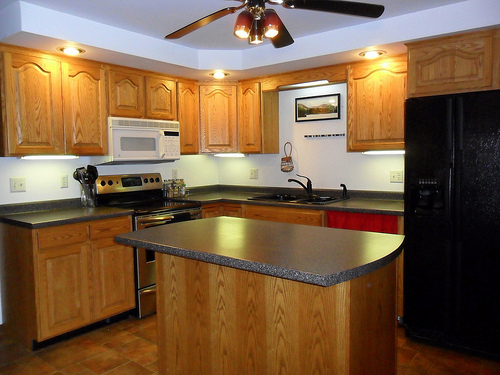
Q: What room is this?
A: It is a kitchen.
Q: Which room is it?
A: It is a kitchen.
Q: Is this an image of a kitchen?
A: Yes, it is showing a kitchen.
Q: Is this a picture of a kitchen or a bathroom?
A: It is showing a kitchen.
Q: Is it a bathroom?
A: No, it is a kitchen.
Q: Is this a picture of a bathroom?
A: No, the picture is showing a kitchen.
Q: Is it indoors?
A: Yes, it is indoors.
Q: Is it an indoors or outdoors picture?
A: It is indoors.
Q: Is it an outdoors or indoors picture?
A: It is indoors.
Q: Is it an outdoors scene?
A: No, it is indoors.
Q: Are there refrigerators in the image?
A: Yes, there is a refrigerator.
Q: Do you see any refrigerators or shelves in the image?
A: Yes, there is a refrigerator.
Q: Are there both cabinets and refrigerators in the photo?
A: Yes, there are both a refrigerator and a cabinet.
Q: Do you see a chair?
A: No, there are no chairs.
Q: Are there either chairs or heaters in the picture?
A: No, there are no chairs or heaters.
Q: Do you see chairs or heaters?
A: No, there are no chairs or heaters.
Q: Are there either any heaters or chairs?
A: No, there are no chairs or heaters.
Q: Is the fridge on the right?
A: Yes, the fridge is on the right of the image.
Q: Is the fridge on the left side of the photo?
A: No, the fridge is on the right of the image.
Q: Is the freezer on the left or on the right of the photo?
A: The freezer is on the right of the image.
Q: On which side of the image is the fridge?
A: The fridge is on the right of the image.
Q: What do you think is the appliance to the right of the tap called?
A: The appliance is a refrigerator.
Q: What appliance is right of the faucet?
A: The appliance is a refrigerator.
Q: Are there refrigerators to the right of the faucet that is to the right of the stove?
A: Yes, there is a refrigerator to the right of the tap.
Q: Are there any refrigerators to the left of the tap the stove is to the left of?
A: No, the refrigerator is to the right of the tap.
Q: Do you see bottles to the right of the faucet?
A: No, there is a refrigerator to the right of the faucet.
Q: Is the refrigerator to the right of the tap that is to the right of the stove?
A: Yes, the refrigerator is to the right of the tap.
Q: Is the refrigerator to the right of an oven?
A: No, the refrigerator is to the right of the tap.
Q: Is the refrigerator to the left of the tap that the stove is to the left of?
A: No, the refrigerator is to the right of the tap.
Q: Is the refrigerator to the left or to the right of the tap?
A: The refrigerator is to the right of the tap.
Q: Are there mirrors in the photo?
A: No, there are no mirrors.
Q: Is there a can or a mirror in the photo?
A: No, there are no mirrors or cans.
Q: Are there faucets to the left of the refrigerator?
A: Yes, there is a faucet to the left of the refrigerator.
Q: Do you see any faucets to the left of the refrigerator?
A: Yes, there is a faucet to the left of the refrigerator.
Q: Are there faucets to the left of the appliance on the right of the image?
A: Yes, there is a faucet to the left of the refrigerator.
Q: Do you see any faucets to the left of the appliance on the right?
A: Yes, there is a faucet to the left of the refrigerator.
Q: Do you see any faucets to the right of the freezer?
A: No, the faucet is to the left of the freezer.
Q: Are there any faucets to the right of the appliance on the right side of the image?
A: No, the faucet is to the left of the freezer.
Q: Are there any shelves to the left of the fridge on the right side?
A: No, there is a faucet to the left of the fridge.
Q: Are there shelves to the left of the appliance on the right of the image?
A: No, there is a faucet to the left of the fridge.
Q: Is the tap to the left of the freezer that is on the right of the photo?
A: Yes, the tap is to the left of the fridge.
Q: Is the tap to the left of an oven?
A: No, the tap is to the left of the fridge.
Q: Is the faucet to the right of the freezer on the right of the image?
A: No, the faucet is to the left of the fridge.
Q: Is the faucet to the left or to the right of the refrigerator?
A: The faucet is to the left of the refrigerator.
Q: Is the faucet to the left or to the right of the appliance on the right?
A: The faucet is to the left of the refrigerator.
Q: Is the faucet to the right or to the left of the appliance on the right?
A: The faucet is to the left of the refrigerator.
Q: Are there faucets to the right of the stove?
A: Yes, there is a faucet to the right of the stove.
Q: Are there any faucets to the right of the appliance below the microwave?
A: Yes, there is a faucet to the right of the stove.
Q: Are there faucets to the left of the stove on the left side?
A: No, the faucet is to the right of the stove.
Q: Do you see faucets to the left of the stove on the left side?
A: No, the faucet is to the right of the stove.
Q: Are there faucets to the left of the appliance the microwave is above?
A: No, the faucet is to the right of the stove.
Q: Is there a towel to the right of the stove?
A: No, there is a faucet to the right of the stove.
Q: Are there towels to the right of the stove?
A: No, there is a faucet to the right of the stove.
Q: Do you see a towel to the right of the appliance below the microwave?
A: No, there is a faucet to the right of the stove.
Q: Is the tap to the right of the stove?
A: Yes, the tap is to the right of the stove.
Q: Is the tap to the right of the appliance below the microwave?
A: Yes, the tap is to the right of the stove.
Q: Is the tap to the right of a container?
A: No, the tap is to the right of the stove.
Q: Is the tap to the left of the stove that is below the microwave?
A: No, the tap is to the right of the stove.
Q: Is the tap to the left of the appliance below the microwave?
A: No, the tap is to the right of the stove.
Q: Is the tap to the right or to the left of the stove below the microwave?
A: The tap is to the right of the stove.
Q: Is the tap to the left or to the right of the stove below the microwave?
A: The tap is to the right of the stove.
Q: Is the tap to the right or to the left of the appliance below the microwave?
A: The tap is to the right of the stove.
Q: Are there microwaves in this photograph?
A: Yes, there is a microwave.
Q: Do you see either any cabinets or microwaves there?
A: Yes, there is a microwave.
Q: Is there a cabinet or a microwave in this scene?
A: Yes, there is a microwave.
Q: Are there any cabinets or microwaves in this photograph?
A: Yes, there is a microwave.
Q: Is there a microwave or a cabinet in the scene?
A: Yes, there is a microwave.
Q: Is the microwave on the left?
A: Yes, the microwave is on the left of the image.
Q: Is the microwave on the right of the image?
A: No, the microwave is on the left of the image.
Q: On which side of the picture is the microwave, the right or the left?
A: The microwave is on the left of the image.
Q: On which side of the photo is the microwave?
A: The microwave is on the left of the image.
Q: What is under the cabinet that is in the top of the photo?
A: The microwave is under the cabinet.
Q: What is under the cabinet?
A: The microwave is under the cabinet.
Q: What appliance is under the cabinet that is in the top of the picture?
A: The appliance is a microwave.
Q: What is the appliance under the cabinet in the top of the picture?
A: The appliance is a microwave.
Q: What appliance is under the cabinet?
A: The appliance is a microwave.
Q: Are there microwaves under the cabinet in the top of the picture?
A: Yes, there is a microwave under the cabinet.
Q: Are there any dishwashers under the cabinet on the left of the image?
A: No, there is a microwave under the cabinet.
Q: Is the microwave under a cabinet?
A: Yes, the microwave is under a cabinet.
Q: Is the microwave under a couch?
A: No, the microwave is under a cabinet.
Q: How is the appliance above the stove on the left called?
A: The appliance is a microwave.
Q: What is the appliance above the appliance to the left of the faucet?
A: The appliance is a microwave.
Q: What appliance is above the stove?
A: The appliance is a microwave.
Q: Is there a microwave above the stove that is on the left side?
A: Yes, there is a microwave above the stove.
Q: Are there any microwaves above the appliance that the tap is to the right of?
A: Yes, there is a microwave above the stove.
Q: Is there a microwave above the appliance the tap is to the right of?
A: Yes, there is a microwave above the stove.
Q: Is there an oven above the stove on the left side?
A: No, there is a microwave above the stove.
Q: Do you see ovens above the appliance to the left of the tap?
A: No, there is a microwave above the stove.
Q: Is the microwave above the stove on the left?
A: Yes, the microwave is above the stove.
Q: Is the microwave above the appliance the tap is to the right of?
A: Yes, the microwave is above the stove.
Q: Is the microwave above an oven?
A: No, the microwave is above the stove.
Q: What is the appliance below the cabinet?
A: The appliance is a microwave.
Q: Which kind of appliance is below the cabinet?
A: The appliance is a microwave.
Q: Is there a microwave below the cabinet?
A: Yes, there is a microwave below the cabinet.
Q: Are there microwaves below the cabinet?
A: Yes, there is a microwave below the cabinet.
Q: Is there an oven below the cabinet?
A: No, there is a microwave below the cabinet.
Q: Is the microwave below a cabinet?
A: Yes, the microwave is below a cabinet.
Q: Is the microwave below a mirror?
A: No, the microwave is below a cabinet.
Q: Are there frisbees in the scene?
A: No, there are no frisbees.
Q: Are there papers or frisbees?
A: No, there are no frisbees or papers.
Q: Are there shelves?
A: No, there are no shelves.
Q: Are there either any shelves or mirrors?
A: No, there are no shelves or mirrors.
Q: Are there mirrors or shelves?
A: No, there are no shelves or mirrors.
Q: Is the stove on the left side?
A: Yes, the stove is on the left of the image.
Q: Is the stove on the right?
A: No, the stove is on the left of the image.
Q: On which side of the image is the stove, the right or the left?
A: The stove is on the left of the image.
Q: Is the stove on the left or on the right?
A: The stove is on the left of the image.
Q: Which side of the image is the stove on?
A: The stove is on the left of the image.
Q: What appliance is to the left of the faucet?
A: The appliance is a stove.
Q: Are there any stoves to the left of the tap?
A: Yes, there is a stove to the left of the tap.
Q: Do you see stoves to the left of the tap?
A: Yes, there is a stove to the left of the tap.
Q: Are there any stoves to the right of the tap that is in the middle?
A: No, the stove is to the left of the faucet.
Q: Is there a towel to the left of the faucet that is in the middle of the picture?
A: No, there is a stove to the left of the tap.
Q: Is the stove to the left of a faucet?
A: Yes, the stove is to the left of a faucet.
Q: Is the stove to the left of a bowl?
A: No, the stove is to the left of a faucet.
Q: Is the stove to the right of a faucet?
A: No, the stove is to the left of a faucet.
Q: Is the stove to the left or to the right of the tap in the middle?
A: The stove is to the left of the faucet.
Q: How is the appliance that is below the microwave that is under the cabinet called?
A: The appliance is a stove.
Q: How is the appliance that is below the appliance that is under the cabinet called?
A: The appliance is a stove.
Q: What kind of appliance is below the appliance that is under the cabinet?
A: The appliance is a stove.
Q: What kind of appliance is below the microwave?
A: The appliance is a stove.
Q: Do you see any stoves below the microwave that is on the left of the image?
A: Yes, there is a stove below the microwave.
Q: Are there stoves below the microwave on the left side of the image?
A: Yes, there is a stove below the microwave.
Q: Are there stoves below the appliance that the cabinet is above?
A: Yes, there is a stove below the microwave.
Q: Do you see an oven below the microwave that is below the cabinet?
A: No, there is a stove below the microwave.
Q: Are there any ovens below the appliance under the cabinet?
A: No, there is a stove below the microwave.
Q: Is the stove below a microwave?
A: Yes, the stove is below a microwave.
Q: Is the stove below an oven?
A: No, the stove is below a microwave.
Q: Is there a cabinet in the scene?
A: Yes, there is a cabinet.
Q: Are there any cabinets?
A: Yes, there is a cabinet.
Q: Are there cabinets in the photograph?
A: Yes, there is a cabinet.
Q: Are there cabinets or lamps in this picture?
A: Yes, there is a cabinet.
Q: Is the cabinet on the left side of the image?
A: Yes, the cabinet is on the left of the image.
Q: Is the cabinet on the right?
A: No, the cabinet is on the left of the image.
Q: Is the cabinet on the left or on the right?
A: The cabinet is on the left of the image.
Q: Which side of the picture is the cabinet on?
A: The cabinet is on the left of the image.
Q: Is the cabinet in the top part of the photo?
A: Yes, the cabinet is in the top of the image.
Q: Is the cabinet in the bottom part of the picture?
A: No, the cabinet is in the top of the image.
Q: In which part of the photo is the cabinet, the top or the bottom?
A: The cabinet is in the top of the image.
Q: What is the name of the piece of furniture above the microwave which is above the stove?
A: The piece of furniture is a cabinet.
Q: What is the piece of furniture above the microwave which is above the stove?
A: The piece of furniture is a cabinet.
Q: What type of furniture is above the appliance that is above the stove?
A: The piece of furniture is a cabinet.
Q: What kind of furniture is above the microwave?
A: The piece of furniture is a cabinet.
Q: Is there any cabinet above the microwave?
A: Yes, there is a cabinet above the microwave.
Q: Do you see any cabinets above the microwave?
A: Yes, there is a cabinet above the microwave.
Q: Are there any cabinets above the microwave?
A: Yes, there is a cabinet above the microwave.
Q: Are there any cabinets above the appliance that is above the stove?
A: Yes, there is a cabinet above the microwave.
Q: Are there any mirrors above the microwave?
A: No, there is a cabinet above the microwave.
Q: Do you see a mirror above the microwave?
A: No, there is a cabinet above the microwave.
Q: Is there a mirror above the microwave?
A: No, there is a cabinet above the microwave.